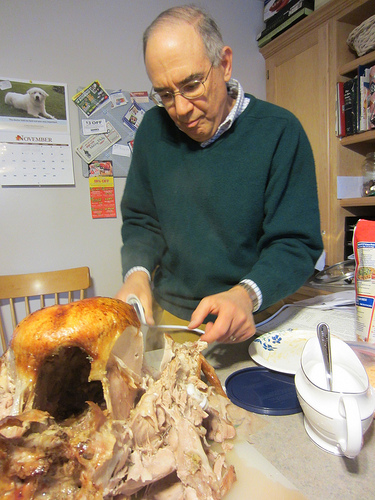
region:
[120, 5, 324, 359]
a man wearing a green sweater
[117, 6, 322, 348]
a man wearing glasses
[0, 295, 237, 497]
a carved turkey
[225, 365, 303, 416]
a plastic blue plid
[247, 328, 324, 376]
a blue and white colored saucer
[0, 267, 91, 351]
brown wooden chair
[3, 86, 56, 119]
a laying white colored dog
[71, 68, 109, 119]
post card on board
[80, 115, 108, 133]
post card on board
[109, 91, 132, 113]
post card on board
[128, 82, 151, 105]
post card on board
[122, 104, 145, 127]
post card on board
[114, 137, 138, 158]
post card on board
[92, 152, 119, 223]
post card on board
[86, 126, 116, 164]
post card on board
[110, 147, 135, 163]
post card on board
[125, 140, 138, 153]
post card on board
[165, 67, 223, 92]
man's bushy eye brows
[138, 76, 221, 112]
glasses on man's face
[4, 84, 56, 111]
white dog on poster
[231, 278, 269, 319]
watch on man's hand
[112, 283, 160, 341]
carving knife in man's hand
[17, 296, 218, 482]
large cut turkey on platter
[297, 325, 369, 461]
white gravy bowl on table top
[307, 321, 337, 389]
silver utensil in bowl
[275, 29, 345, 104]
tall brown cabinet in the background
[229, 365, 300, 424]
brown blue lid on surface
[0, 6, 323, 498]
Man looking at partially eaten turkey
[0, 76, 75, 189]
Calendar on the wall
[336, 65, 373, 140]
Books on the shelf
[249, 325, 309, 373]
White plate with blue flowers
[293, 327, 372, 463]
White gravy boat on the table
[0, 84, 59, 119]
Picture of dog on the calendar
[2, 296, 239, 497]
Partially-carved turkey on the table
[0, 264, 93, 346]
Wooden chair against the wall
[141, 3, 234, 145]
Balding grey-haired man with glasses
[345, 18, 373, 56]
Wicker basket on the top shelf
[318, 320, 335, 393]
the utensil is silver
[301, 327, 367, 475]
utensil in the dish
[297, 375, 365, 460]
the dish is white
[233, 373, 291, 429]
the lid is blue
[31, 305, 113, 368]
the skin is brown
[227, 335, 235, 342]
ring on the finger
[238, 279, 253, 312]
the watch is silver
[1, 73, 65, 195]
calendar on the wall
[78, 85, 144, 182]
coupons on the board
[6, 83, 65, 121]
dog on the calendar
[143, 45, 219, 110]
A pair of eyeglasses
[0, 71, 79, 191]
A calendar on the wall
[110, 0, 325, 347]
Man is wearing a green sweater